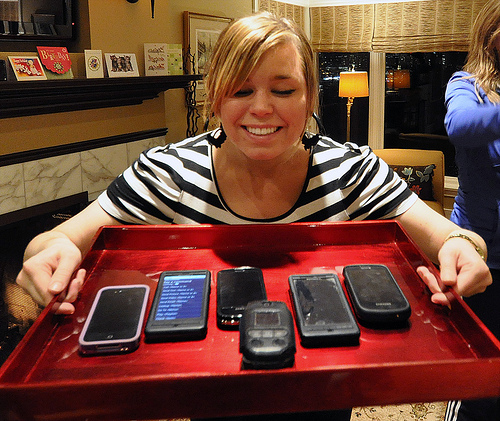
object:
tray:
[2, 221, 499, 419]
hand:
[413, 232, 494, 313]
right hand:
[10, 243, 87, 316]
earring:
[298, 112, 327, 151]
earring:
[202, 112, 227, 150]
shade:
[338, 71, 372, 100]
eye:
[231, 86, 254, 97]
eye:
[269, 83, 298, 98]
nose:
[251, 92, 274, 117]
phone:
[218, 266, 264, 322]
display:
[0, 218, 500, 421]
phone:
[341, 263, 411, 328]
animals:
[109, 54, 118, 72]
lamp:
[337, 68, 374, 148]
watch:
[438, 230, 485, 263]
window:
[385, 53, 461, 151]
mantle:
[1, 71, 201, 119]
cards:
[6, 54, 47, 82]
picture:
[180, 10, 245, 106]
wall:
[3, 3, 258, 196]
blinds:
[308, 3, 376, 49]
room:
[1, 1, 500, 401]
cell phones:
[237, 301, 296, 369]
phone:
[285, 272, 361, 348]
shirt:
[96, 133, 415, 222]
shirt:
[447, 71, 497, 274]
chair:
[370, 147, 446, 208]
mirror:
[2, 1, 74, 38]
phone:
[144, 268, 213, 342]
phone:
[72, 284, 148, 356]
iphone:
[76, 282, 152, 356]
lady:
[12, 11, 499, 314]